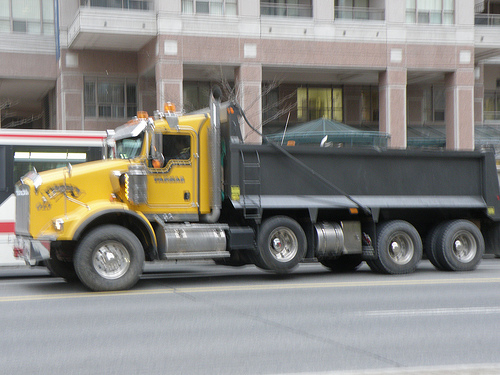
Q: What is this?
A: LORRY.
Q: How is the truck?
A: In motion.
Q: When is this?
A: Daytime.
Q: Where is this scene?
A: On a city street.